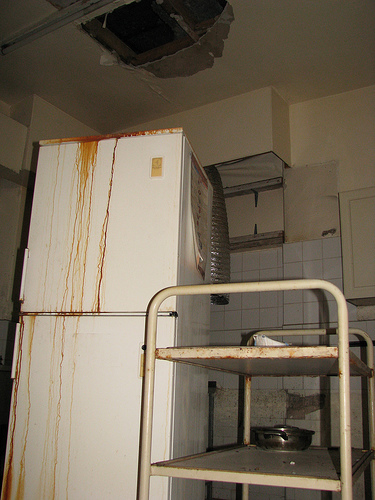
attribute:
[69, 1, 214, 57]
hole — large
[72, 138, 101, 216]
rust — brown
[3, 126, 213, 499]
fridge — white, moved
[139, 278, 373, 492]
shelves — metal, rusted, white, dirty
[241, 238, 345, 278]
wall — tiled, torn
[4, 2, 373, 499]
room — shambles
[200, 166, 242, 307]
ducting — falling, hanging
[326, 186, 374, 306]
cabinet — attached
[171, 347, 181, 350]
edge — brown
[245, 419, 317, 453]
hotpot — metal, black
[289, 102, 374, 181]
wall — tan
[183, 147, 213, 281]
paper — attached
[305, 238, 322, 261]
tile — white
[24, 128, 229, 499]
refrigerator — dirty, white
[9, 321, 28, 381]
handle — white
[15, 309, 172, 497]
door — dirty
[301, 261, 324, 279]
tile — white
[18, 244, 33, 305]
handle — white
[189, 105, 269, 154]
wall — tan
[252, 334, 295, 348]
paper — white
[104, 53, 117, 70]
spot — white